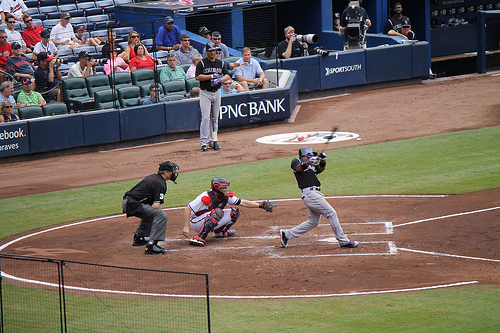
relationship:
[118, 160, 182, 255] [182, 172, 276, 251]
umpire behind catcher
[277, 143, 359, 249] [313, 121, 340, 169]
batter swinging bat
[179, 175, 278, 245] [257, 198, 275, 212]
catcher wearing glove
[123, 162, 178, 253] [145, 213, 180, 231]
umpire wearing pants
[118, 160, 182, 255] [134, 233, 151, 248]
umpire wearing shoe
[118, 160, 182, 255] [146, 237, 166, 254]
umpire wearing shoe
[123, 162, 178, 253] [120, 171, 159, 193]
umpire wearing shirt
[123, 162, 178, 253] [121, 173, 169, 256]
umpire wearing clothes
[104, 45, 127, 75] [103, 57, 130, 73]
person with person top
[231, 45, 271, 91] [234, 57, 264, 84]
man with shirt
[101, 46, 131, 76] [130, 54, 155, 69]
woman wearing top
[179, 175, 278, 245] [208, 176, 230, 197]
catcher in head gear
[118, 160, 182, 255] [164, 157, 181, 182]
umpire in head gear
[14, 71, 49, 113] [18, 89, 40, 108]
man in shirt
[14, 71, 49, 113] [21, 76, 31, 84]
man with hat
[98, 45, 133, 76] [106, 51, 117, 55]
woman wearing sunglasses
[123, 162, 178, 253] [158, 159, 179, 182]
umpire wearing head gear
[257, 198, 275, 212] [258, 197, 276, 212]
glove wearing glove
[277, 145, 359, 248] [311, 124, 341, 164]
batter swinging bat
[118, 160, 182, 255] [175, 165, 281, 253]
umpire standing behind catcher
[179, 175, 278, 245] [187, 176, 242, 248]
catcher wearing catcher uniform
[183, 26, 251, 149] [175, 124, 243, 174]
player at bat